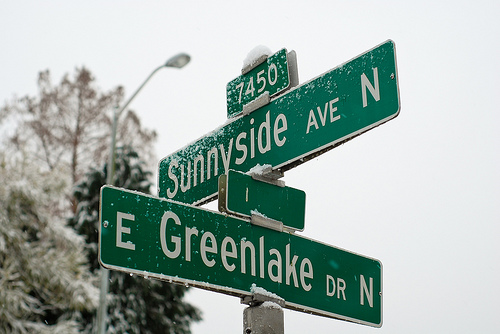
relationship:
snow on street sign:
[239, 42, 273, 67] [95, 40, 397, 326]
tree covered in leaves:
[0, 63, 206, 333] [12, 61, 103, 138]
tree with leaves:
[0, 63, 206, 333] [108, 283, 185, 324]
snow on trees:
[28, 97, 75, 256] [0, 61, 107, 332]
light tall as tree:
[95, 47, 191, 332] [0, 63, 206, 333]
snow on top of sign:
[239, 42, 273, 67] [226, 47, 293, 112]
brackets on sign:
[253, 167, 289, 185] [156, 39, 401, 206]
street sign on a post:
[104, 218, 404, 258] [233, 268, 293, 334]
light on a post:
[95, 52, 191, 332] [122, 54, 233, 155]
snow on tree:
[0, 66, 157, 330] [0, 63, 206, 333]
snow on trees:
[0, 95, 145, 334] [38, 100, 110, 160]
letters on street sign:
[110, 224, 348, 274] [59, 74, 446, 274]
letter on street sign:
[236, 64, 289, 104] [224, 47, 288, 119]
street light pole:
[0, 55, 500, 334] [86, 284, 127, 329]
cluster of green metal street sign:
[98, 37, 400, 332] [225, 48, 288, 115]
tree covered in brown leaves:
[19, 87, 76, 272] [2, 76, 147, 268]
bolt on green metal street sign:
[103, 219, 110, 228] [92, 182, 386, 328]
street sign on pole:
[0, 55, 500, 334] [241, 52, 285, 332]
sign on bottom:
[98, 184, 385, 328] [96, 250, 386, 294]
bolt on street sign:
[101, 216, 113, 233] [95, 180, 385, 328]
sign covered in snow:
[225, 47, 290, 119] [237, 40, 275, 72]